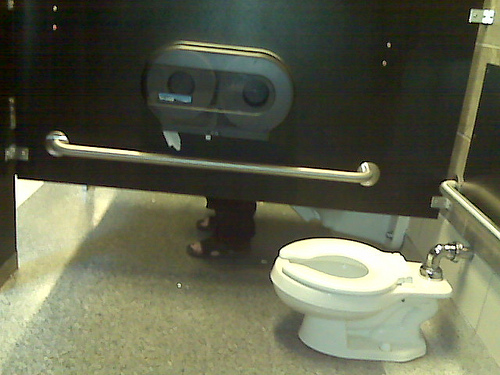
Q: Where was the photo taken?
A: In a bathroom.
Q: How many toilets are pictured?
A: One.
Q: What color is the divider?
A: Black.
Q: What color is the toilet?
A: White.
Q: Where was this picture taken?
A: Bathroom.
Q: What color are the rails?
A: Silver.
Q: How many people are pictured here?
A: Zero.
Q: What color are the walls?
A: Tan.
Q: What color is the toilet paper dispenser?
A: Black.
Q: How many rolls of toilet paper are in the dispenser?
A: Two.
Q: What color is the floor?
A: Grey.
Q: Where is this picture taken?
A: Bathroom.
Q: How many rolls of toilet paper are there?
A: 2.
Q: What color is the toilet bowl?
A: White.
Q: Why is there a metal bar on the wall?
A: Handrail.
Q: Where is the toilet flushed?
A: It flushes automatically.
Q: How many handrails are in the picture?
A: 2.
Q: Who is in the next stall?
A: A woman.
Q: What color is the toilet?
A: White.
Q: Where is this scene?
A: A public bathroom.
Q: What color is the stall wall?
A: Black.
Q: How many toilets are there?
A: One.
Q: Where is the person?
A: In the next stall.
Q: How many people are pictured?
A: One.